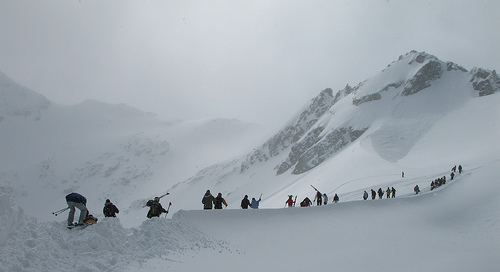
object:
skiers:
[286, 194, 296, 207]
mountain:
[150, 45, 500, 202]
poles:
[142, 194, 180, 217]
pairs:
[198, 191, 226, 212]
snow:
[99, 128, 210, 179]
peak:
[360, 41, 444, 79]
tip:
[379, 45, 457, 113]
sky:
[0, 0, 500, 120]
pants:
[68, 201, 89, 226]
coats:
[62, 193, 88, 203]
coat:
[286, 199, 295, 204]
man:
[57, 192, 91, 228]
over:
[65, 192, 90, 227]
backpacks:
[103, 207, 115, 216]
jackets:
[202, 193, 217, 208]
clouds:
[88, 43, 270, 165]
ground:
[153, 199, 497, 272]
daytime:
[0, 0, 500, 272]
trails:
[457, 165, 465, 173]